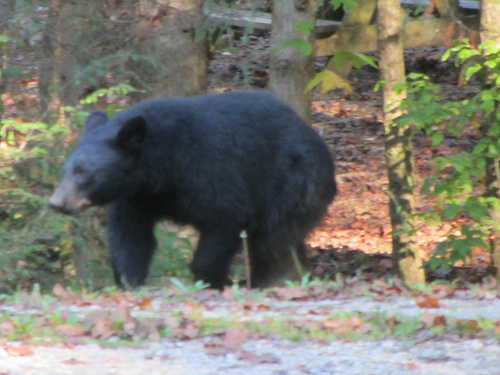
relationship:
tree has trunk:
[266, 2, 427, 289] [376, 3, 428, 281]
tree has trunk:
[268, 2, 314, 132] [268, 3, 310, 126]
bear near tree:
[47, 90, 341, 292] [266, 2, 427, 289]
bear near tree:
[47, 90, 341, 292] [375, 2, 425, 290]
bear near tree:
[47, 90, 341, 292] [268, 2, 314, 132]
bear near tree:
[47, 90, 341, 292] [124, 0, 210, 100]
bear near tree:
[47, 90, 341, 292] [415, 1, 483, 45]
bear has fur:
[47, 90, 341, 292] [70, 87, 340, 288]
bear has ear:
[47, 90, 341, 292] [117, 114, 146, 150]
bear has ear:
[47, 90, 341, 292] [82, 108, 112, 136]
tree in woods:
[375, 2, 425, 290] [0, 2, 500, 374]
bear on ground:
[47, 90, 341, 292] [0, 0, 497, 375]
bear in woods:
[47, 90, 341, 292] [0, 2, 500, 374]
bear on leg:
[47, 90, 341, 292] [190, 168, 248, 286]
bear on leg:
[47, 90, 341, 292] [102, 204, 157, 288]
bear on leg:
[47, 90, 341, 292] [251, 195, 341, 287]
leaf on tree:
[272, 34, 299, 53] [266, 2, 427, 289]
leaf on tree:
[454, 44, 479, 68] [375, 2, 425, 290]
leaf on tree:
[467, 85, 493, 106] [375, 2, 425, 290]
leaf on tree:
[470, 140, 491, 161] [375, 2, 425, 290]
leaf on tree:
[465, 199, 485, 219] [375, 2, 425, 290]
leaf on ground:
[54, 281, 75, 302] [0, 0, 497, 375]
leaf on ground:
[92, 313, 115, 333] [0, 0, 497, 375]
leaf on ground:
[137, 296, 154, 315] [0, 0, 497, 375]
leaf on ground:
[218, 318, 247, 348] [0, 0, 497, 375]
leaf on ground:
[413, 290, 440, 311] [0, 0, 497, 375]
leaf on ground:
[267, 284, 302, 296] [0, 0, 497, 375]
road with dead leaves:
[5, 277, 495, 373] [0, 284, 498, 367]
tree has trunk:
[375, 2, 425, 290] [349, 7, 425, 277]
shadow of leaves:
[298, 246, 489, 274] [255, 0, 497, 294]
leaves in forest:
[255, 0, 497, 294] [2, 5, 496, 279]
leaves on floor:
[317, 120, 394, 294] [310, 98, 386, 250]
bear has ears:
[47, 90, 341, 292] [82, 108, 147, 150]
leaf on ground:
[365, 210, 376, 230] [0, 0, 497, 375]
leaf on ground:
[348, 196, 359, 203] [0, 0, 497, 375]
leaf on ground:
[344, 170, 372, 187] [0, 0, 497, 375]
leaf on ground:
[344, 147, 361, 157] [0, 0, 497, 375]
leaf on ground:
[424, 159, 431, 166] [0, 0, 497, 375]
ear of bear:
[114, 115, 149, 153] [47, 90, 341, 292]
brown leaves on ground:
[307, 95, 491, 292] [0, 81, 499, 373]